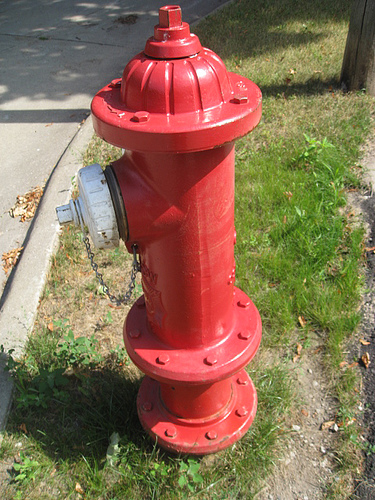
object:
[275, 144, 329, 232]
grass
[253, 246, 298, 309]
grass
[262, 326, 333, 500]
dirt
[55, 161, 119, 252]
cap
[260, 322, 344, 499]
patch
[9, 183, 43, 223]
leaves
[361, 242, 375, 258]
leaves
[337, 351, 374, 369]
leaves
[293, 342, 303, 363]
leaves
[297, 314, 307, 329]
leaves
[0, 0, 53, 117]
ground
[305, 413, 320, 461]
soil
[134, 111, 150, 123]
bolts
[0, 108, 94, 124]
shadow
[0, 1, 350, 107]
shadow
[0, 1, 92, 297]
road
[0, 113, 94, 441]
concrete curb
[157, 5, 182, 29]
bolt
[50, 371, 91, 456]
grass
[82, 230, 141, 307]
chain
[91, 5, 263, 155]
cap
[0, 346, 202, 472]
shadow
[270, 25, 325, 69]
grass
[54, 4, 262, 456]
fire hydrant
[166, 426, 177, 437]
bolt